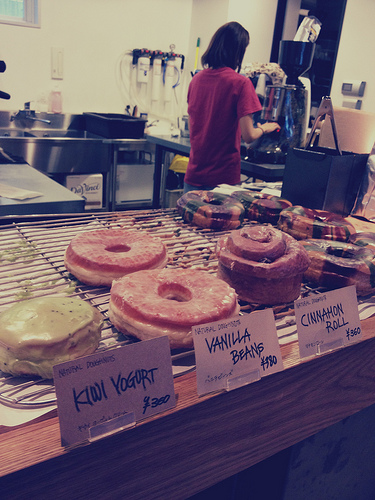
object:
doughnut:
[108, 262, 241, 348]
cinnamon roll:
[216, 223, 309, 304]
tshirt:
[183, 66, 262, 188]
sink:
[0, 126, 112, 174]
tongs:
[303, 95, 343, 156]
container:
[279, 145, 368, 216]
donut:
[176, 189, 246, 230]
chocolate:
[180, 192, 201, 216]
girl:
[183, 22, 282, 194]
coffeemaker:
[247, 39, 317, 164]